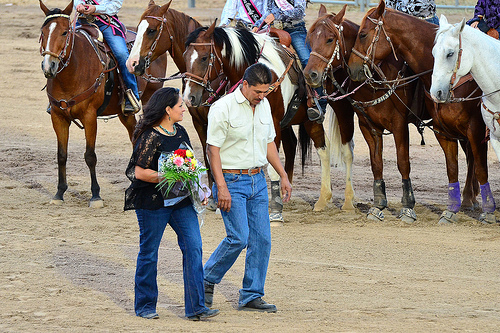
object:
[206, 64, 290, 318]
people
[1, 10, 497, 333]
ground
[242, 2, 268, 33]
sash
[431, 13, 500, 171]
horse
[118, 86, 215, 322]
woman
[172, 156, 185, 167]
flower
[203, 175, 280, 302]
jean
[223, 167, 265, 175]
belt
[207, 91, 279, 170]
shirt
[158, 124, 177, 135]
necklace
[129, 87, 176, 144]
hair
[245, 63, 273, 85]
hair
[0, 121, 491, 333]
sand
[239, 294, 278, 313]
shoe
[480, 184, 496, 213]
cloth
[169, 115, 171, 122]
earring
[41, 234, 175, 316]
shadow